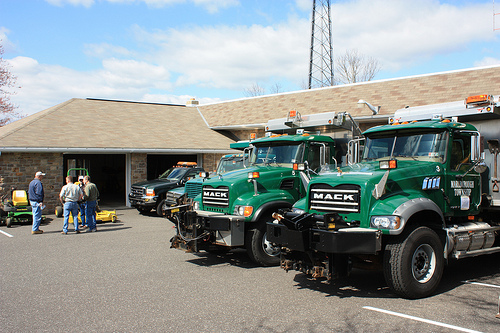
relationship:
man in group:
[82, 176, 99, 231] [21, 167, 106, 233]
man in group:
[60, 172, 84, 233] [21, 167, 106, 233]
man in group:
[75, 175, 85, 187] [21, 167, 106, 233]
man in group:
[28, 171, 46, 235] [21, 167, 106, 233]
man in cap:
[28, 171, 46, 235] [26, 165, 56, 179]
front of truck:
[128, 177, 158, 212] [130, 162, 195, 219]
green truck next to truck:
[162, 110, 372, 267] [163, 131, 257, 251]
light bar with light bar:
[177, 162, 197, 167] [175, 158, 197, 167]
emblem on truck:
[304, 182, 359, 214] [273, 72, 495, 279]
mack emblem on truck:
[204, 183, 228, 208] [195, 110, 352, 264]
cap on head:
[35, 171, 45, 176] [31, 155, 58, 184]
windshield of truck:
[364, 132, 462, 163] [266, 93, 498, 298]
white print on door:
[450, 179, 474, 199] [435, 130, 490, 215]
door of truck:
[435, 130, 490, 215] [291, 113, 458, 275]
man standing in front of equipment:
[21, 168, 52, 247] [0, 189, 46, 228]